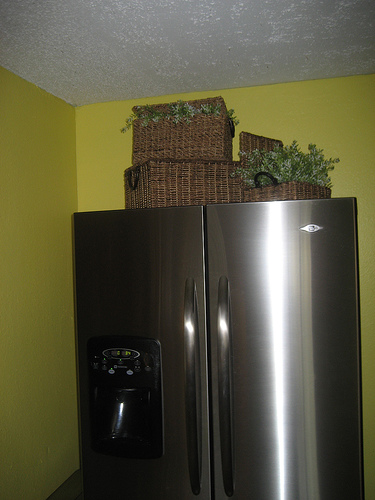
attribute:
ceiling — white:
[57, 35, 215, 80]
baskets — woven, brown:
[123, 96, 331, 207]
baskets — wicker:
[99, 97, 349, 213]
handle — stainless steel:
[212, 269, 239, 498]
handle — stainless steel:
[206, 288, 243, 473]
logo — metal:
[299, 222, 324, 232]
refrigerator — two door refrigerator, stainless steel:
[71, 210, 348, 493]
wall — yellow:
[337, 79, 360, 120]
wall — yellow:
[75, 70, 373, 498]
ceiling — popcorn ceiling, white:
[2, 1, 373, 106]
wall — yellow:
[0, 65, 79, 498]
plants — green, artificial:
[228, 139, 340, 187]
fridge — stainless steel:
[70, 197, 364, 498]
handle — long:
[216, 274, 236, 498]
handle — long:
[181, 277, 202, 498]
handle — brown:
[197, 262, 244, 498]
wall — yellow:
[37, 75, 373, 353]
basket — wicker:
[239, 132, 331, 202]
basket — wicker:
[131, 95, 235, 164]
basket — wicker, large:
[124, 157, 241, 207]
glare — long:
[264, 198, 293, 498]